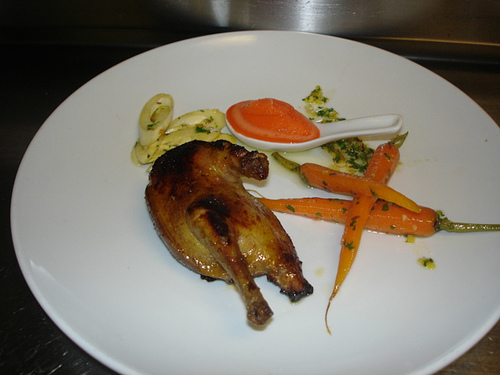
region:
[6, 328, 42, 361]
this is a table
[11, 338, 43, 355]
the table is wooden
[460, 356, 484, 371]
the table is brown in color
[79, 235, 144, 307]
this is a plate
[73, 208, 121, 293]
the plate is white in color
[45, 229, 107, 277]
the plate is clean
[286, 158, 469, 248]
these are some carrots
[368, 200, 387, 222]
the carrot is orange in color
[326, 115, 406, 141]
this is a spoon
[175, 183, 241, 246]
the meat is oily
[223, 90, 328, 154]
Orange food stuff in a spoon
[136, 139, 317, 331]
Oily fried chice serving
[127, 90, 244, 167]
White colored pieces of vegetable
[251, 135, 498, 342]
Three pieces of chillies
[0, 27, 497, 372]
Wide dish on the table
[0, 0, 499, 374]
Wide dish with food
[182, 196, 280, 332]
Cooked leg of a chicken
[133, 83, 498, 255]
Different foods covered with green vegetable sprinklings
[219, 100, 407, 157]
Short white colored spoon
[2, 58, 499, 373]
Dark black table with white and grey strands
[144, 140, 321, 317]
piece of chicken on white plate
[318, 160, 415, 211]
orange carrot on plate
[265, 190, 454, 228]
orange carrot on plate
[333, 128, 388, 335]
orange carrot on plate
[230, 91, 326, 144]
orange food on white spoon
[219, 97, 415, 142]
white spoon on white plate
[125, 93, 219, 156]
mussels on white plate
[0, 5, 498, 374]
white plate on wood table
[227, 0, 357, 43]
light shining on wood table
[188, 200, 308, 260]
golden skin of chicken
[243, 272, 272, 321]
part of a thigh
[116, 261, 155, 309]
part of a plate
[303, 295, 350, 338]
part fo a tip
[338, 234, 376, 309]
part of a plate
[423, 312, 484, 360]
edge of a plate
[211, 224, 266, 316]
part of a thigh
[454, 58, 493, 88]
this is a table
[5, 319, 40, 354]
the table is wooden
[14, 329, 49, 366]
the table is brown in color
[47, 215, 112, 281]
this is a plate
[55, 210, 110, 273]
the plate is white in color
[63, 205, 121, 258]
the plate is round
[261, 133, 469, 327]
these are some carrots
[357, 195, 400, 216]
the carrots are orange in color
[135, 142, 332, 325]
this is some chicken